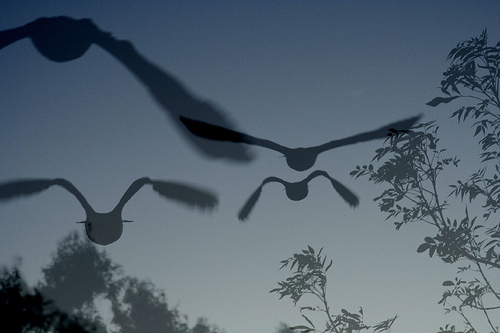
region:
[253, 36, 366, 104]
Blue sky behind the birds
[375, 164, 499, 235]
Leaves on a tree brance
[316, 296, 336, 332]
Tree branch by the birds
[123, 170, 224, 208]
Wing of a bird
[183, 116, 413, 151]
Bird flapping its wings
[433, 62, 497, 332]
Plants beside the birds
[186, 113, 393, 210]
Two birds in the sky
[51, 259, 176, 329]
Trees beneath a bird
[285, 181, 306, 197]
Body of a bird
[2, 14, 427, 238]
Four birds in the sky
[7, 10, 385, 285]
Group of birds flying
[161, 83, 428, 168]
Birds wings are outstretched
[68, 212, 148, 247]
The bird is holding a stick in its mouth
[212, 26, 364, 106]
The sun is going down and its dark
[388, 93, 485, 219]
Leaves on a tree in the background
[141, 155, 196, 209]
The wing is very fluffy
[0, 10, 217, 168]
The bird is flying toward the camera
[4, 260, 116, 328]
The treeline is very black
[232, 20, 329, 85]
The sky is clear no clouds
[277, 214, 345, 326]
The branch has lots of leaves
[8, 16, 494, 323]
birds flying in the air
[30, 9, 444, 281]
birds flying in the sky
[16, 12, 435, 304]
a bird flying high in the sky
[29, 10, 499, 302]
birds flapping their wings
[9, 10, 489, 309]
shadow of four birds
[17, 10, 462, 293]
four birds in the sky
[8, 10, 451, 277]
four birds in the air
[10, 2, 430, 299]
four birds flapping their wings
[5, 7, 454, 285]
four birds flying together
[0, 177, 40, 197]
the blurred wing of a bird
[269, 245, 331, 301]
leaves on a tree blowing in the wind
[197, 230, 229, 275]
an area of gray sky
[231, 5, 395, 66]
an area of darker blue sky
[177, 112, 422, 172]
a bird with its wings spread to full length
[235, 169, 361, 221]
a bird with its wings in an m shape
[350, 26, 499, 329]
a tall tree to the right of a bird's wing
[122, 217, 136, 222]
a black line protruding from the right side of a bird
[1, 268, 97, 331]
an area of dark leaves in front of a lighter shaded tree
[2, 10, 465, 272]
Drones in air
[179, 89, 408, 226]
Drones are grey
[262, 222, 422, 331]
Trees are dark grey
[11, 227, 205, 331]
Something is fuzzy.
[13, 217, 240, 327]
Something is large and grey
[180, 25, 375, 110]
The sky is light grey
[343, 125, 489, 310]
The trees have stems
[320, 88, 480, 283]
The trees have leaves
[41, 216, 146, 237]
The drone has spikes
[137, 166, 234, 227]
The drone has fuzzy wings.